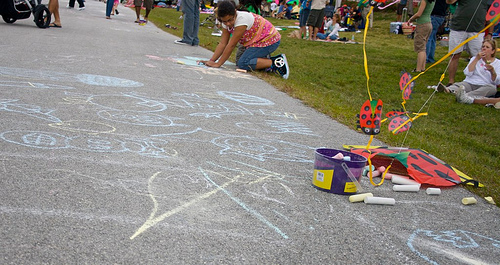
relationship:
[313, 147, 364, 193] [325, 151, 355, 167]
bucket filled with chalk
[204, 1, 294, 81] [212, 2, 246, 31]
girl has a head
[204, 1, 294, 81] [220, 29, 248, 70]
girl has an arm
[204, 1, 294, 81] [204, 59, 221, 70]
girl has a hand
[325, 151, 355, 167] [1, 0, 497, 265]
chalk on pavement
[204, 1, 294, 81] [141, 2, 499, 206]
girl sitting on grass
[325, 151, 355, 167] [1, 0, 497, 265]
chalk drawn on pavement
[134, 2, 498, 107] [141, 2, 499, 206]
people are standing on grass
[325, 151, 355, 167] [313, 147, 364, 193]
chalk next to bucket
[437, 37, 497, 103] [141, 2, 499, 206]
woman sitting on grass